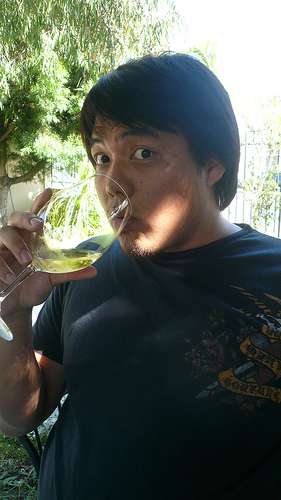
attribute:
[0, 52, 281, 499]
man — male, drinking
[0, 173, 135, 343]
wine — white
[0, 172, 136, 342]
glass — large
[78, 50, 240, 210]
hair — black, straight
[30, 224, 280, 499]
shirt — black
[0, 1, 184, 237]
tree — gree, large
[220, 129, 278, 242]
fence — metal